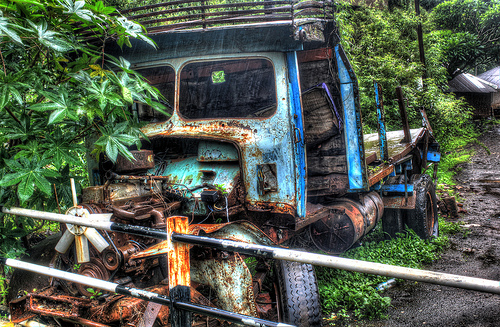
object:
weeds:
[337, 242, 385, 307]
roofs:
[447, 58, 498, 92]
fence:
[65, 1, 336, 31]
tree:
[14, 20, 139, 195]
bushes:
[0, 2, 172, 201]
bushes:
[346, 7, 496, 129]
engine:
[56, 153, 233, 258]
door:
[286, 56, 362, 208]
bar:
[0, 206, 500, 325]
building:
[447, 68, 499, 126]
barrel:
[307, 191, 385, 253]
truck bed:
[359, 125, 433, 178]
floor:
[29, 261, 89, 316]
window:
[179, 61, 276, 119]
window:
[110, 67, 174, 120]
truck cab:
[85, 28, 364, 223]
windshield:
[174, 58, 274, 117]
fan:
[54, 177, 114, 264]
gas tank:
[315, 192, 384, 254]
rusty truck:
[8, 5, 439, 327]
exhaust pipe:
[345, 243, 368, 250]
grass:
[322, 235, 409, 304]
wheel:
[383, 174, 439, 242]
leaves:
[12, 22, 144, 143]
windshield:
[124, 61, 173, 124]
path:
[372, 131, 500, 327]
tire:
[269, 245, 319, 327]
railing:
[83, 32, 345, 56]